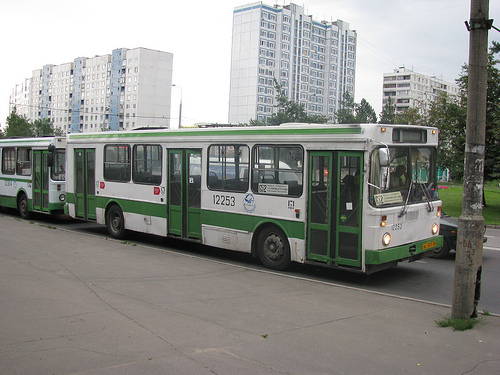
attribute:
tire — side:
[252, 218, 295, 276]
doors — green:
[307, 152, 368, 271]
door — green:
[304, 147, 364, 271]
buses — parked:
[1, 118, 449, 285]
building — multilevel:
[227, 0, 359, 130]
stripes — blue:
[104, 42, 122, 132]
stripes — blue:
[69, 55, 84, 130]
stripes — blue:
[37, 62, 48, 129]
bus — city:
[46, 109, 439, 318]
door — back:
[62, 147, 88, 219]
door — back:
[74, 136, 110, 223]